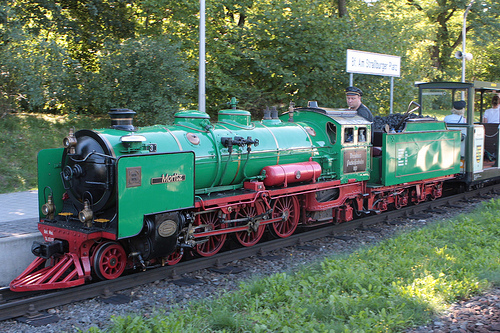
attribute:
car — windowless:
[412, 79, 498, 191]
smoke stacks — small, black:
[100, 101, 152, 136]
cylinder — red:
[257, 159, 325, 187]